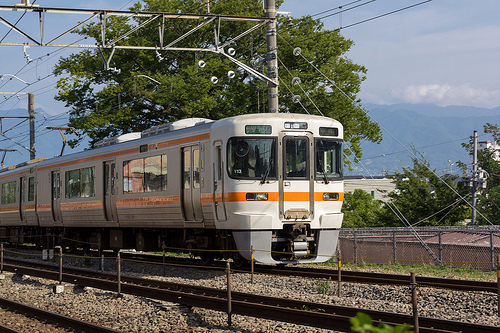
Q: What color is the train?
A: Grey.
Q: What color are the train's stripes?
A: Orange.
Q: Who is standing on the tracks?
A: No one.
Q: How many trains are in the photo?
A: One.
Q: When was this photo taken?
A: Daytime.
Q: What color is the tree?
A: Green.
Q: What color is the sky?
A: Blue.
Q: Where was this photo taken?
A: Train tracks.